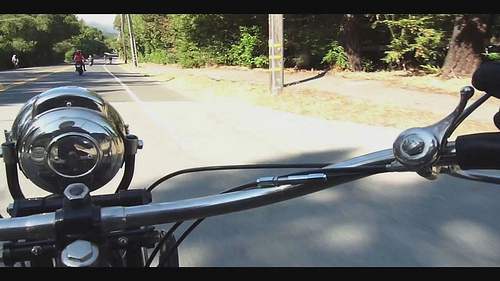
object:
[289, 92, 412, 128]
grass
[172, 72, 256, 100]
grass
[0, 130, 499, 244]
handlebar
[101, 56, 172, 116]
line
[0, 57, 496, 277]
road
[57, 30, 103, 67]
trees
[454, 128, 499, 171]
handle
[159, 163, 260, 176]
wire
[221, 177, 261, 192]
wire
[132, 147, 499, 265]
shadow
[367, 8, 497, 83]
tree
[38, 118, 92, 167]
reflection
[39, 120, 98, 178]
motorcyclist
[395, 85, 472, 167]
brake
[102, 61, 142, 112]
line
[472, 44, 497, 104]
hand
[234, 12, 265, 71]
trees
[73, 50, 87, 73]
motorcyclist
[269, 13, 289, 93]
pole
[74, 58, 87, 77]
motorbike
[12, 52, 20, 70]
person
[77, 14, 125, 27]
sky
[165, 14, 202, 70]
trees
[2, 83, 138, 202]
headlight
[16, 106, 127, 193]
back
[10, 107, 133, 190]
mirror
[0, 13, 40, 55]
tree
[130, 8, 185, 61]
tree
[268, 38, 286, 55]
line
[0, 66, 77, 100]
line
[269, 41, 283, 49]
mark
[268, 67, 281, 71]
mark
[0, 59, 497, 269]
ground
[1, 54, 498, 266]
bike